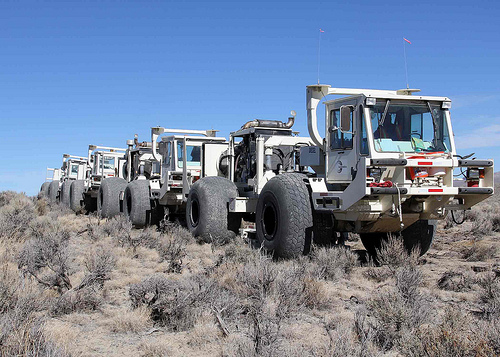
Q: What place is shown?
A: It is a desert.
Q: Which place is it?
A: It is a desert.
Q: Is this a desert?
A: Yes, it is a desert.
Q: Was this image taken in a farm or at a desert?
A: It was taken at a desert.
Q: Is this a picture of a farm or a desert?
A: It is showing a desert.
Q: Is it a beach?
A: No, it is a desert.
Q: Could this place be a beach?
A: No, it is a desert.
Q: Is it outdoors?
A: Yes, it is outdoors.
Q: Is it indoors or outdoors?
A: It is outdoors.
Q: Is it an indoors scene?
A: No, it is outdoors.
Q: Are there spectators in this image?
A: No, there are no spectators.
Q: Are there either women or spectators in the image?
A: No, there are no spectators or women.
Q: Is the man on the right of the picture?
A: Yes, the man is on the right of the image.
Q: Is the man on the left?
A: No, the man is on the right of the image.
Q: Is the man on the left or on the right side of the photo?
A: The man is on the right of the image.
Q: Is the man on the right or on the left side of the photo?
A: The man is on the right of the image.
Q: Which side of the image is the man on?
A: The man is on the right of the image.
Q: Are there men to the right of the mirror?
A: Yes, there is a man to the right of the mirror.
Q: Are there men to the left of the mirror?
A: No, the man is to the right of the mirror.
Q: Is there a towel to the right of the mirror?
A: No, there is a man to the right of the mirror.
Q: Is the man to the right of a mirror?
A: Yes, the man is to the right of a mirror.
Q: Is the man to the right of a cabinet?
A: No, the man is to the right of a mirror.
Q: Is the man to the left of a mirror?
A: No, the man is to the right of a mirror.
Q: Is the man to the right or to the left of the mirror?
A: The man is to the right of the mirror.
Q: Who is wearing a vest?
A: The man is wearing a vest.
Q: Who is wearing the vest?
A: The man is wearing a vest.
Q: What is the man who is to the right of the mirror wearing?
A: The man is wearing a vest.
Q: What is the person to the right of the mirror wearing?
A: The man is wearing a vest.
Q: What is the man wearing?
A: The man is wearing a vest.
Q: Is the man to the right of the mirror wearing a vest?
A: Yes, the man is wearing a vest.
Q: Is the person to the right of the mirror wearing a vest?
A: Yes, the man is wearing a vest.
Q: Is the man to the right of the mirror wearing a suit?
A: No, the man is wearing a vest.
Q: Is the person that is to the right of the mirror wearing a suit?
A: No, the man is wearing a vest.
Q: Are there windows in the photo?
A: Yes, there is a window.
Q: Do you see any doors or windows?
A: Yes, there is a window.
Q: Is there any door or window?
A: Yes, there is a window.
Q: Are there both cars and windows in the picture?
A: Yes, there are both a window and a car.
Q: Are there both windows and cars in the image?
A: Yes, there are both a window and a car.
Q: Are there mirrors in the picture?
A: Yes, there is a mirror.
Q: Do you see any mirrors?
A: Yes, there is a mirror.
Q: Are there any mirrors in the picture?
A: Yes, there is a mirror.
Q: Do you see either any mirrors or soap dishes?
A: Yes, there is a mirror.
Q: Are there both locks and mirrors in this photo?
A: No, there is a mirror but no locks.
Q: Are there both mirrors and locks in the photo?
A: No, there is a mirror but no locks.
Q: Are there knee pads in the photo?
A: No, there are no knee pads.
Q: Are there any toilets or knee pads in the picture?
A: No, there are no knee pads or toilets.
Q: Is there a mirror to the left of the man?
A: Yes, there is a mirror to the left of the man.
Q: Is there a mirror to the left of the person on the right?
A: Yes, there is a mirror to the left of the man.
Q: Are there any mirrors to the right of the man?
A: No, the mirror is to the left of the man.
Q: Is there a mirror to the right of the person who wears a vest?
A: No, the mirror is to the left of the man.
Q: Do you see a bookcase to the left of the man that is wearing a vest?
A: No, there is a mirror to the left of the man.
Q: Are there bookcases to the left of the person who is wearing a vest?
A: No, there is a mirror to the left of the man.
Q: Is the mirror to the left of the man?
A: Yes, the mirror is to the left of the man.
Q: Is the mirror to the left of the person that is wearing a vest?
A: Yes, the mirror is to the left of the man.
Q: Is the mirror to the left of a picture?
A: No, the mirror is to the left of the man.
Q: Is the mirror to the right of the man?
A: No, the mirror is to the left of the man.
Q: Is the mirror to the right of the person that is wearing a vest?
A: No, the mirror is to the left of the man.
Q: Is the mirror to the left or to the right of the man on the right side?
A: The mirror is to the left of the man.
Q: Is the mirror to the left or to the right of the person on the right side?
A: The mirror is to the left of the man.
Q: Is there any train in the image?
A: No, there are no trains.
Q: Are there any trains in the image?
A: No, there are no trains.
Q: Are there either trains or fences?
A: No, there are no trains or fences.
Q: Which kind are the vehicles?
A: The vehicles are cars.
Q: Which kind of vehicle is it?
A: The vehicles are cars.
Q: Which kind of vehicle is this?
A: These are cars.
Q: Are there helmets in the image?
A: No, there are no helmets.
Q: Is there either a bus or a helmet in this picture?
A: No, there are no helmets or buses.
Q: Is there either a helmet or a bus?
A: No, there are no helmets or buses.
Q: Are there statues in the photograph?
A: No, there are no statues.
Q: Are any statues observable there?
A: No, there are no statues.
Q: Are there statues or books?
A: No, there are no statues or books.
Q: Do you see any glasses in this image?
A: No, there are no glasses.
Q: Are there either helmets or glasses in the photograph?
A: No, there are no glasses or helmets.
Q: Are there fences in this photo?
A: No, there are no fences.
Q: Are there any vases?
A: No, there are no vases.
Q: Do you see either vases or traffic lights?
A: No, there are no vases or traffic lights.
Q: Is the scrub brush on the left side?
A: Yes, the scrub brush is on the left of the image.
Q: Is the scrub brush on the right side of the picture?
A: No, the scrub brush is on the left of the image.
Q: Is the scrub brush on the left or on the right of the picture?
A: The scrub brush is on the left of the image.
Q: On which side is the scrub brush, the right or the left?
A: The scrub brush is on the left of the image.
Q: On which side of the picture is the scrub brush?
A: The scrub brush is on the left of the image.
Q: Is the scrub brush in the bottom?
A: Yes, the scrub brush is in the bottom of the image.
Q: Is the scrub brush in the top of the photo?
A: No, the scrub brush is in the bottom of the image.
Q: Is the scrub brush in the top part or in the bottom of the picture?
A: The scrub brush is in the bottom of the image.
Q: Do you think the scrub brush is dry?
A: Yes, the scrub brush is dry.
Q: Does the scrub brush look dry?
A: Yes, the scrub brush is dry.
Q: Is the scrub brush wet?
A: No, the scrub brush is dry.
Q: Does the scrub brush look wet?
A: No, the scrub brush is dry.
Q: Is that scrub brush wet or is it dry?
A: The scrub brush is dry.